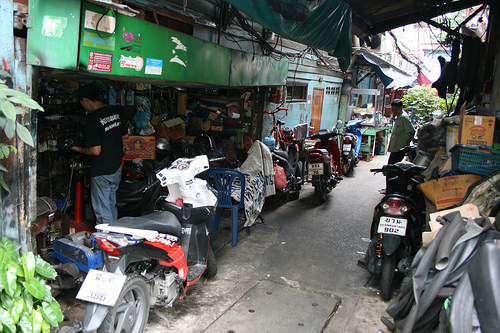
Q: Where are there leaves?
A: Left side of photo.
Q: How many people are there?
A: Two.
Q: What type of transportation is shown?
A: Motorcycles.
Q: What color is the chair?
A: Blue.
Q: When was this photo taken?
A: During the day.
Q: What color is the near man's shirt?
A: Black.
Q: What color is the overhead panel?
A: Green.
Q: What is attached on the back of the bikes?
A: License plates.